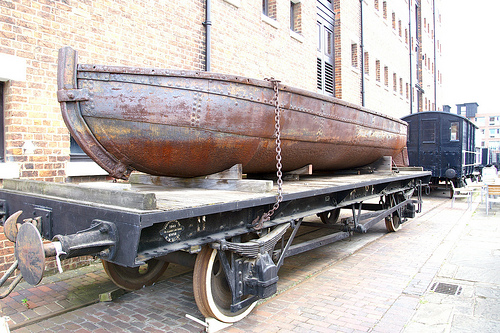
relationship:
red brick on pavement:
[4, 171, 498, 331] [1, 177, 498, 331]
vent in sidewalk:
[429, 280, 462, 296] [220, 184, 498, 331]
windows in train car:
[417, 113, 439, 140] [396, 93, 484, 193]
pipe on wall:
[203, 0, 213, 72] [0, 0, 442, 287]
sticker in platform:
[160, 220, 183, 245] [1, 164, 498, 325]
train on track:
[1, 43, 498, 330] [14, 264, 240, 331]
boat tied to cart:
[39, 38, 424, 174] [2, 173, 437, 289]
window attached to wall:
[347, 39, 362, 73] [0, 0, 442, 287]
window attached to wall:
[360, 49, 373, 78] [0, 0, 442, 287]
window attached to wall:
[376, 54, 382, 86] [0, 0, 442, 287]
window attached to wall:
[383, 65, 391, 89] [0, 0, 442, 287]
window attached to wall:
[399, 75, 406, 98] [0, 0, 442, 287]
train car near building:
[401, 111, 478, 198] [0, 0, 445, 287]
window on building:
[289, 1, 304, 41] [0, 0, 445, 287]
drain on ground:
[427, 279, 480, 307] [327, 267, 379, 297]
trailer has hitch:
[2, 143, 437, 325] [5, 185, 99, 271]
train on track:
[0, 111, 497, 323] [10, 175, 455, 331]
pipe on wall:
[200, 0, 220, 62] [133, 3, 287, 69]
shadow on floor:
[24, 292, 231, 331] [0, 165, 500, 333]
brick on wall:
[78, 307, 178, 331] [95, 10, 167, 50]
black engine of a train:
[401, 110, 478, 187] [1, 43, 498, 330]